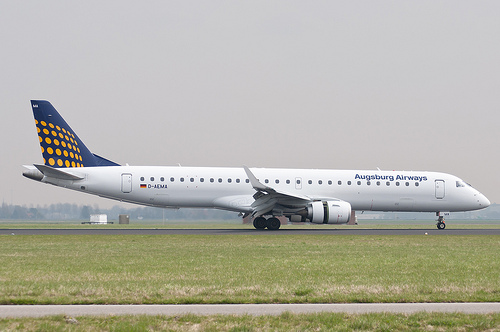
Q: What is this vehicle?
A: Plane.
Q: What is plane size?
A: Large.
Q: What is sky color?
A: Grey.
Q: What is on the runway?
A: Airplane.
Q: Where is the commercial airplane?
A: On the runway.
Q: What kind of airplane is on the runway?
A: A passenger plane.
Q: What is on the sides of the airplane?
A: Windows.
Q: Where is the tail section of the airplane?
A: In the back.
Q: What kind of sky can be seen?
A: Gray and cloudy.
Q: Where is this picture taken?
A: Airport.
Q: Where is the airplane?
A: On the tarmac.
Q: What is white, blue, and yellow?
A: Airplane.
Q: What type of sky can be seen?
A: Overcast.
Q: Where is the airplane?
A: On the runway.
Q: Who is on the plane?
A: Passengers.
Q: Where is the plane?
A: On the tarmac.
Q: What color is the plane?
A: White.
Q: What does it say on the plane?
A: Augsburg Airways.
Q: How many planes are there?
A: One.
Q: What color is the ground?
A: Green.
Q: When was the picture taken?
A: In the daytime.